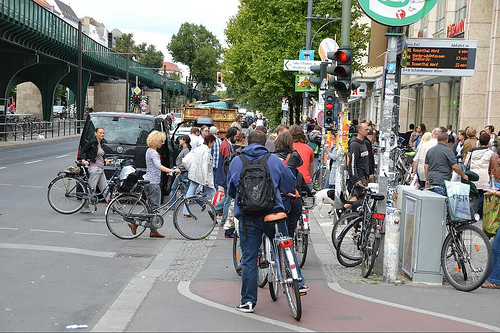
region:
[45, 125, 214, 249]
Two woman walking their bikes across the street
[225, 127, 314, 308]
Man with a black backpack on his back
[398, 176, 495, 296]
A bike leaning against a large grey box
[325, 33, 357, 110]
Traffic signal with the red light on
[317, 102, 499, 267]
Sidewalk crowded with many people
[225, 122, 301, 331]
Man wearing a blue sweatshirt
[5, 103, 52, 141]
Bike rack intended for bikes to be parked there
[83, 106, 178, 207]
Black car parked in the street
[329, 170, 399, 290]
Bike parked against a light pole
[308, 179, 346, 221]
White dog walking on the sidewalk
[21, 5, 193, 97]
green bridge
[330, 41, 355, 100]
red signal light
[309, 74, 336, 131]
red signal light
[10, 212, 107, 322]
gray pavement with white stripes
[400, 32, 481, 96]
gray and black sign with orange lights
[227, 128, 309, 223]
man wearing black backpack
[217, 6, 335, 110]
brown tree with green leaves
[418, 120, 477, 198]
older man with gray shirt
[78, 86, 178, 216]
black truck with reflection in rear window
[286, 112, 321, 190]
woman wearing red shirt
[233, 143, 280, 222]
man's black back pack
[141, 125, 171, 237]
woman with blonde frizzy hair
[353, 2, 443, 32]
round green sign on a street corner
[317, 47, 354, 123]
two traffic lights showing red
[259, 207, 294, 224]
orange seat of a bicycle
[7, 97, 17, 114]
person sitting at a picnic table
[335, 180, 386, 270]
bikes leaning up against a pole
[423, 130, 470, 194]
man wearing a grey tee shirt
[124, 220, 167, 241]
brown colored boots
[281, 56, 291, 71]
blue arrow on a white sign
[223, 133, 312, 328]
man in blue on bike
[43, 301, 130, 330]
small white spot in street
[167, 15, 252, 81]
large green tree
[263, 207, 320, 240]
pink seat on bike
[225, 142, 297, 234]
black back pack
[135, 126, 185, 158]
man with bushy blond hair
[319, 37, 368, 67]
red traffic light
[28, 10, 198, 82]
large green bridge over head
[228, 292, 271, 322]
white and black sneakers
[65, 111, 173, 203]
shiny black van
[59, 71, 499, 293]
many people walking down the street and sidewalk